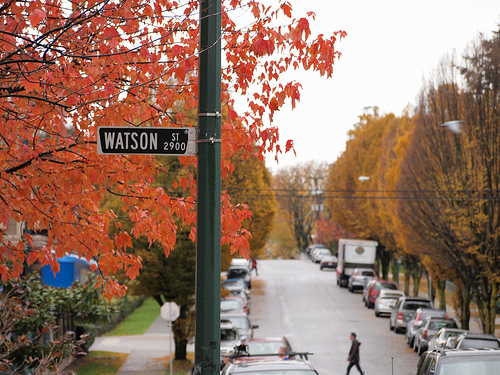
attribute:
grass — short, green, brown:
[69, 294, 168, 375]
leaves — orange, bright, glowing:
[37, 43, 183, 116]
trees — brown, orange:
[323, 66, 499, 277]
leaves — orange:
[333, 153, 477, 237]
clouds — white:
[352, 14, 424, 80]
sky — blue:
[218, 2, 463, 165]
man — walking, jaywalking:
[336, 328, 375, 374]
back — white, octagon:
[158, 299, 183, 321]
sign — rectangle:
[93, 125, 206, 159]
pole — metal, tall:
[194, 2, 237, 370]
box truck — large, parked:
[333, 234, 381, 282]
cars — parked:
[320, 245, 499, 375]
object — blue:
[44, 254, 100, 288]